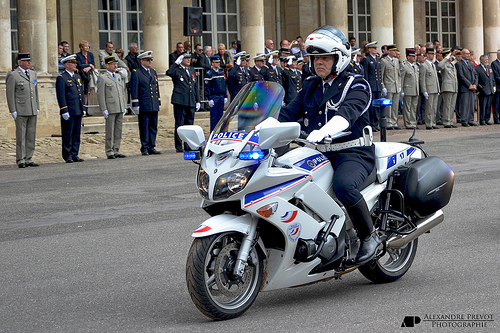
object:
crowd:
[4, 36, 500, 168]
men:
[4, 52, 42, 168]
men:
[54, 53, 88, 164]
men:
[97, 55, 130, 159]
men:
[131, 49, 165, 156]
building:
[1, 0, 498, 129]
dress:
[271, 71, 382, 177]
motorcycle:
[173, 81, 451, 322]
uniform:
[276, 70, 377, 207]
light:
[184, 150, 200, 160]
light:
[372, 97, 393, 106]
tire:
[183, 229, 265, 322]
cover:
[191, 214, 283, 263]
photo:
[0, 0, 498, 332]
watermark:
[398, 313, 497, 329]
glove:
[305, 114, 351, 143]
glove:
[251, 116, 280, 139]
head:
[309, 47, 351, 78]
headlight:
[212, 163, 261, 202]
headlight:
[196, 164, 210, 202]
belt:
[315, 136, 372, 152]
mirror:
[258, 121, 302, 149]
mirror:
[176, 124, 206, 151]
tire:
[357, 208, 419, 284]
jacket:
[76, 51, 96, 71]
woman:
[75, 39, 96, 116]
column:
[138, 0, 172, 78]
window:
[97, 0, 124, 53]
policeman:
[273, 23, 386, 266]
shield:
[207, 80, 285, 151]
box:
[390, 151, 457, 220]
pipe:
[385, 205, 442, 249]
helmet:
[303, 25, 352, 81]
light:
[239, 150, 266, 160]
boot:
[345, 195, 389, 267]